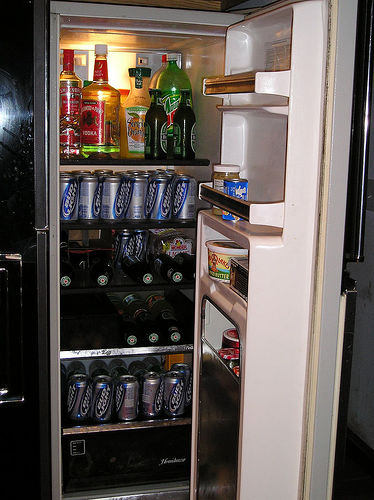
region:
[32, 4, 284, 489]
The inside of a refrigerator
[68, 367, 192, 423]
These are cans of beer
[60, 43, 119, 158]
Bottles of vodka are on the top shelf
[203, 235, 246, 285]
A tub of margarine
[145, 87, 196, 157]
Bottles of beer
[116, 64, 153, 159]
A bottle of orange juice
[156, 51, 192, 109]
This is a bottle of soda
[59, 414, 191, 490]
The crisper drawer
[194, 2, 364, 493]
The refrigerator door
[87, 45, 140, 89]
This is the refrigerator's light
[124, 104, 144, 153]
the label is orange white and green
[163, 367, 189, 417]
the can is silver blue and white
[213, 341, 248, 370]
the lid is red and white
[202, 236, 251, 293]
the tub has red yellow blue and green on it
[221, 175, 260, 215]
the container is blue and white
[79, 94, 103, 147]
the label is red white and black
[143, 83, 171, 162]
the bottle is dark green in color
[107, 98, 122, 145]
the liquid is yellow in color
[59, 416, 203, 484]
the draw is black and silver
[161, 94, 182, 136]
the label is red green and white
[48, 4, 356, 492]
an open refrigerator door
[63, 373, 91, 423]
a blue can of beer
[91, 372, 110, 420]
a blue can of beer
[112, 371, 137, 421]
a blue can of beer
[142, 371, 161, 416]
a blue can of beer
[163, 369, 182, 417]
a blue can of beer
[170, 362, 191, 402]
a blue can of beer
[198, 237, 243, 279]
a tub of butter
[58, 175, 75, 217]
a blue can of beer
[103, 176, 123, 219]
a blue can of beer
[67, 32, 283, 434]
drinks and items inside a refrigerator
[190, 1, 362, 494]
white refrigerator is open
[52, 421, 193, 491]
drawer on the bottom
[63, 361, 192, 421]
light beer in cans on the shelf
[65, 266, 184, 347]
beer with green caps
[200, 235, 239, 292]
dish of butter in door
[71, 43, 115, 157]
vodka on the top shelf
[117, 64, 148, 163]
large bottle orange juice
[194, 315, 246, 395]
jellies and cheese in the door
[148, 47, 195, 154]
mountain dew is behind the beer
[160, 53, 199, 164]
two liter mountain dew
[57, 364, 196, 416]
shelf of bud lights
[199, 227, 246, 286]
container of butter in fridge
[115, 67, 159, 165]
simply orange orange juice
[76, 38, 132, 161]
big bottle of vodka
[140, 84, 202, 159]
two bottles of beer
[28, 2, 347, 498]
refrigerator full of drinks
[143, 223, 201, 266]
loaf of wonder bread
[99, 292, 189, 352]
three bottles of beer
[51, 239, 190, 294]
four bottles of beer